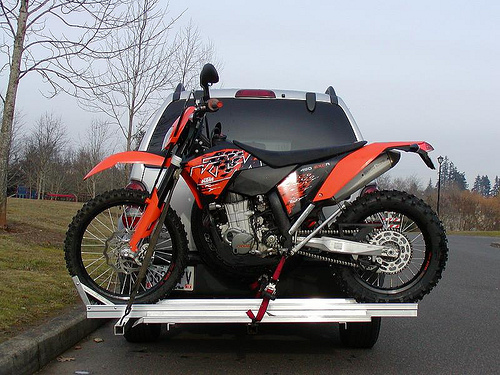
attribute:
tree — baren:
[80, 8, 190, 156]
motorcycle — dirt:
[47, 59, 442, 342]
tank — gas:
[265, 148, 380, 220]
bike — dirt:
[140, 161, 372, 287]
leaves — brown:
[142, 28, 179, 57]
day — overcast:
[315, 23, 410, 79]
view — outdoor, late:
[49, 21, 178, 172]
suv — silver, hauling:
[261, 73, 374, 143]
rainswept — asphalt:
[448, 245, 481, 308]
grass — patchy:
[15, 244, 53, 317]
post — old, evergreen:
[430, 122, 469, 214]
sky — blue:
[267, 21, 317, 55]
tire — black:
[71, 173, 174, 244]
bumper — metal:
[174, 265, 354, 318]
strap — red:
[218, 257, 286, 369]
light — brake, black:
[232, 59, 288, 113]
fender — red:
[90, 152, 198, 175]